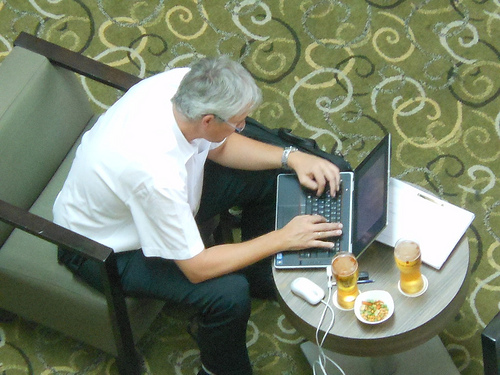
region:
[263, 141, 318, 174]
A man wearing a silver watch.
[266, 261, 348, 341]
A computer mouse attached to a laptop.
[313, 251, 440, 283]
Two glasses of beer on a table.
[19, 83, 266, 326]
A man sitting on a chair.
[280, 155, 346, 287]
A man typing on a laptop.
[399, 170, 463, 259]
A folder sitting on a table.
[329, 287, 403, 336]
A bowl sitting next to two glasses.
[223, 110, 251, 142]
a man wearing eyeglasses.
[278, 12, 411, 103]
Swirly designs decorating a carpet.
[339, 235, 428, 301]
Two glasses sitting on top of coastes.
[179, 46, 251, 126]
man with salt and pepper hair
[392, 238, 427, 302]
glass full of amber colored drink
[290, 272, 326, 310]
white computer mouse on a table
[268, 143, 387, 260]
man typing on a lap top computer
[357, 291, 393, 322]
small white dish with bar snacks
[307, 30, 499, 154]
carpet is green with multicolored swirls design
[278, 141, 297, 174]
man wearing a silver watch on his wrist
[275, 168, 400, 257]
black lap top is turned on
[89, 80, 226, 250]
man is wearing a plain white tee shirt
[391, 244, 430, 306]
glass is sitting on a coaster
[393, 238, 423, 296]
a tall glass on the table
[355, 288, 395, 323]
a white bowl on the table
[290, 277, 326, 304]
a white computer mouse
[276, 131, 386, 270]
a laptop on the table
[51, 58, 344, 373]
a man wearing a white shirt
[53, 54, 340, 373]
a man typing on a laptop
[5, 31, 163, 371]
a grey chair with dark colored arms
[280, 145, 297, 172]
a watch the man is wearing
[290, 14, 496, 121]
the colorful carpet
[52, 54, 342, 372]
a man with grey hair wearing glasses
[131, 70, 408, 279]
A man on the laptop.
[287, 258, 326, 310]
Mouse on the table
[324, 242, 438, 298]
Two glasses on beer on the table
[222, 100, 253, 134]
The man is wearing glasses.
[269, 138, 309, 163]
The man is wearing a watch.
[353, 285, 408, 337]
food in the small bowl.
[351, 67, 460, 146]
designs in the carpet.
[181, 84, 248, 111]
The man hair is gray.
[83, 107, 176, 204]
The man is wearing a white shirt.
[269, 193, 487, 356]
A round table in front of the man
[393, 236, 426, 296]
A light brown beer in a glass furthest from a man.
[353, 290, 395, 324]
A small white bowl of snacks.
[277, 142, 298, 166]
Silver watch on a man's left wrist.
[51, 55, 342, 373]
A grey haired man in navy blue jeans and a white shirt.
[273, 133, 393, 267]
A silver and black laptop.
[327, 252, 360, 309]
Beer on a table close to a man.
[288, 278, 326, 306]
A white mouse on a table.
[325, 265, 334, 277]
The white USB on the end of a mouse cord.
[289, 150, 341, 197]
The right hand of a man.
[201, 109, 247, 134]
The glasses on a man's face.